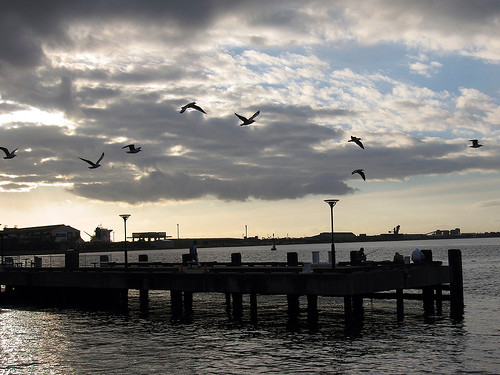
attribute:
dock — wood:
[1, 247, 465, 332]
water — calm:
[1, 235, 498, 375]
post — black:
[123, 217, 129, 272]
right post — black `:
[329, 205, 337, 270]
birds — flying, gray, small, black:
[1, 99, 485, 184]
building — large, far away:
[0, 222, 82, 251]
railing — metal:
[0, 251, 114, 271]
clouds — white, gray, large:
[1, 1, 500, 206]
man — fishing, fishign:
[357, 245, 388, 264]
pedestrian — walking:
[188, 238, 204, 271]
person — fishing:
[409, 246, 428, 265]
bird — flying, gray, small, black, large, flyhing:
[0, 145, 20, 163]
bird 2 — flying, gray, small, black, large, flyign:
[76, 151, 105, 171]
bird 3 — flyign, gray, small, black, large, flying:
[120, 141, 142, 156]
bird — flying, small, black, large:
[177, 98, 208, 118]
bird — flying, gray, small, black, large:
[346, 133, 366, 153]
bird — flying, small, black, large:
[350, 165, 369, 185]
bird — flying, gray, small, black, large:
[467, 135, 485, 153]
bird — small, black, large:
[233, 108, 262, 129]